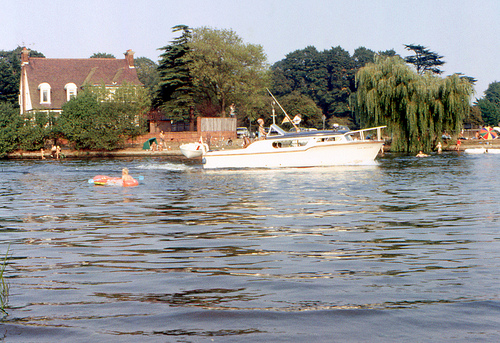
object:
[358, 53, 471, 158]
willow tree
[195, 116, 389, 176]
boat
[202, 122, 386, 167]
boat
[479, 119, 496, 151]
umbrella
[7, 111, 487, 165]
beach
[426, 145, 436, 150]
ground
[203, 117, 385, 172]
boat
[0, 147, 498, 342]
water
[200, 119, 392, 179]
boat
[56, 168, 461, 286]
water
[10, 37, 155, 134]
house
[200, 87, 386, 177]
boat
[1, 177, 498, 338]
waves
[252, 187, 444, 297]
water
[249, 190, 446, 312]
back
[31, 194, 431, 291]
lake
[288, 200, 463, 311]
water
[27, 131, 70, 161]
people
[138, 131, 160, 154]
tent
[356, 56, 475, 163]
tree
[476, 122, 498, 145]
umbrella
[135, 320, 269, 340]
ripples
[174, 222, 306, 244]
ripples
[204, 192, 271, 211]
ripples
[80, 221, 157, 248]
ripples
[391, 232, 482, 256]
ripples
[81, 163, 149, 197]
floating person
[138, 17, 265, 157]
tree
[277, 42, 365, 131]
tree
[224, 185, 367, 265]
water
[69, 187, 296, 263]
water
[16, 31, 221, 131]
houses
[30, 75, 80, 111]
white windows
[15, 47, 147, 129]
house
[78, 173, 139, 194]
float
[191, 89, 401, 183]
boat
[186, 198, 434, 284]
water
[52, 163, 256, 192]
people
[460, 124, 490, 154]
shore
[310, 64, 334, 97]
leaves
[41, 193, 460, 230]
water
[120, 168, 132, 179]
man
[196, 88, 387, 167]
boat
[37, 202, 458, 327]
water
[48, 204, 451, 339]
water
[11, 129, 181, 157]
wall